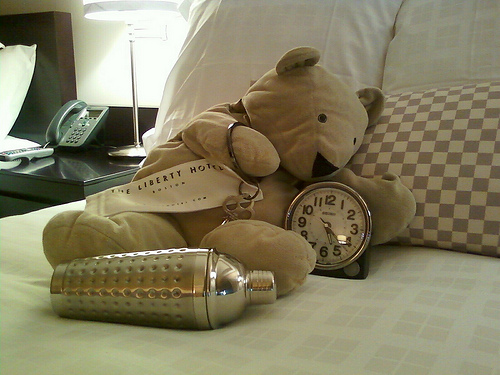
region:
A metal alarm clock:
[286, 182, 371, 283]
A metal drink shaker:
[49, 249, 278, 333]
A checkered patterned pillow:
[362, 87, 498, 258]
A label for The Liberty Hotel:
[84, 159, 256, 206]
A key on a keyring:
[219, 118, 257, 230]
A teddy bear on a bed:
[32, 42, 422, 294]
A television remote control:
[0, 149, 59, 163]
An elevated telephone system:
[41, 97, 119, 156]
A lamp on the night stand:
[76, 0, 190, 162]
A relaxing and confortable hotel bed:
[1, 187, 498, 374]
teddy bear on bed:
[82, 36, 424, 258]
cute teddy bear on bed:
[117, 44, 452, 239]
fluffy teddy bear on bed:
[173, 13, 434, 293]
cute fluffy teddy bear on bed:
[151, 8, 437, 307]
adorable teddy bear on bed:
[123, 34, 437, 316]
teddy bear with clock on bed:
[111, 26, 450, 263]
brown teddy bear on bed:
[120, 46, 448, 268]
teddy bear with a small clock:
[143, 23, 425, 273]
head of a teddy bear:
[249, 38, 386, 176]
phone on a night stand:
[12, 76, 115, 170]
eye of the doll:
[298, 107, 339, 130]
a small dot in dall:
[307, 108, 335, 128]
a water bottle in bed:
[44, 245, 359, 343]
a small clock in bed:
[297, 153, 389, 270]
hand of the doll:
[215, 126, 310, 198]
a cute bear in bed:
[30, 73, 400, 373]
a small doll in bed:
[23, 60, 470, 359]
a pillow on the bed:
[364, 68, 498, 224]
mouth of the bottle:
[245, 263, 292, 325]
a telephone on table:
[23, 71, 124, 166]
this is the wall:
[84, 53, 109, 73]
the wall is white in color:
[79, 50, 101, 77]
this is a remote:
[4, 143, 58, 160]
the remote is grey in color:
[0, 143, 58, 162]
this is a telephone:
[36, 100, 109, 155]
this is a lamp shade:
[79, 0, 195, 165]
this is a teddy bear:
[39, 44, 416, 297]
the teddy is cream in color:
[293, 87, 325, 104]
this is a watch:
[291, 188, 378, 279]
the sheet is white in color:
[376, 306, 436, 343]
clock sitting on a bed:
[281, 179, 373, 282]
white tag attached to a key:
[76, 160, 267, 229]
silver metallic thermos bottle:
[46, 239, 281, 331]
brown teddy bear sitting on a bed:
[37, 41, 419, 310]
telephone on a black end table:
[42, 93, 110, 153]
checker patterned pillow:
[347, 78, 498, 253]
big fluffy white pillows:
[158, 1, 498, 158]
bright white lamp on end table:
[73, 2, 181, 164]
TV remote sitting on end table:
[1, 141, 58, 167]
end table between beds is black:
[3, 132, 145, 207]